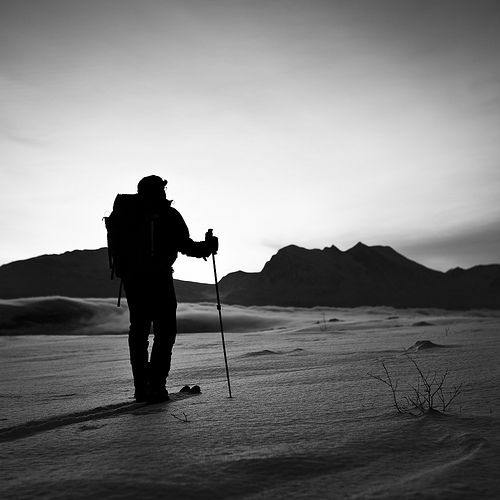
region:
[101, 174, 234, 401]
a cross-country skier looking at the horizon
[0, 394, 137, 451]
tracks of cross-country skis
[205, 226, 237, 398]
ski pole in skier's right hand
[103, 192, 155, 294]
backpack worn by a skier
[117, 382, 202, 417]
cross-country skis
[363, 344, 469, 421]
small leafless shrub in the snow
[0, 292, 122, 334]
low rise covered by snow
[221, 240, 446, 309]
mountain on the horizon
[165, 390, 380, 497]
smooth snowy surface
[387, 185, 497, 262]
cloud on the horizon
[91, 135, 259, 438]
Man standing in the snow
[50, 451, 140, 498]
Snow covering the ground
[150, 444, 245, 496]
Snow covering the ground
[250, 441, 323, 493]
Snow covering the ground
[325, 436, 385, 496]
Snow covering the ground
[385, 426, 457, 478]
Snow covering the ground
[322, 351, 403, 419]
Snow covering the ground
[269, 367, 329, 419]
Snow covering the ground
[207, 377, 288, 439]
Snow covering the ground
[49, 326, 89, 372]
Snow covering the ground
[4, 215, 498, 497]
rocky landscape with sands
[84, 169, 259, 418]
a hiker crossing the rocky landscape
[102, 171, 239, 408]
a hiker holding a walking stick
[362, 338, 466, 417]
couple small tree branches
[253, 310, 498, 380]
a landscape with lot of sand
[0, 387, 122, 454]
shadow of a hiker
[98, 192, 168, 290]
a hiker's backpack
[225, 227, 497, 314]
a rocky mountain range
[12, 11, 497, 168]
a clear sky with no clouds